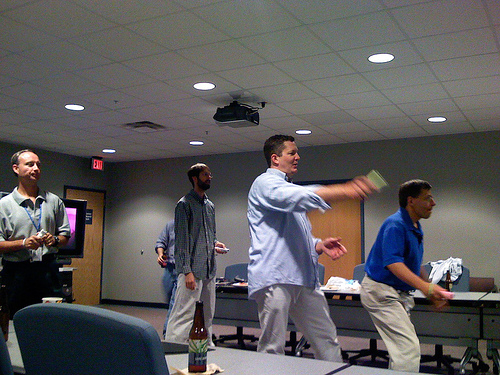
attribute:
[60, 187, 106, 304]
door — wooden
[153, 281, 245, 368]
bottle — dark, brown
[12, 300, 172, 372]
chair — blue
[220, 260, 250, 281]
chair — blue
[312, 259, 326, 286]
chair — blue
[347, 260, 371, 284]
chair — blue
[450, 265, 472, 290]
chair — blue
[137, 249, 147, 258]
protector — wall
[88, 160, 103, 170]
sign — exit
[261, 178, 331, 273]
shirt — light, blue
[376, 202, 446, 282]
man — blue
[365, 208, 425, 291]
shirt — bright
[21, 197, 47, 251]
lanyard — blue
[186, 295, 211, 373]
bottle — brown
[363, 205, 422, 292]
shirt — blue, short sleeve